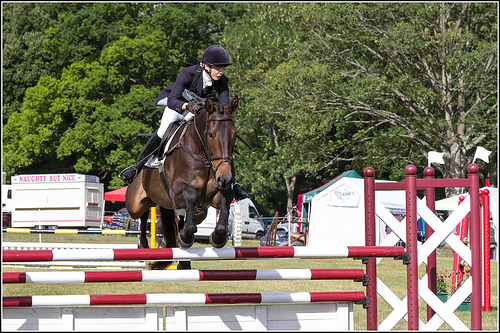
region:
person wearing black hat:
[161, 42, 228, 119]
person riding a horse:
[136, 40, 253, 245]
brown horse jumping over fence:
[126, 102, 251, 252]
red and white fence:
[7, 240, 357, 327]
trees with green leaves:
[10, 10, 150, 155]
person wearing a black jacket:
[168, 37, 235, 121]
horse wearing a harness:
[193, 95, 240, 187]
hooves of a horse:
[171, 218, 233, 253]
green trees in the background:
[245, 3, 496, 173]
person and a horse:
[125, 40, 242, 257]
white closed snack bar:
[9, 165, 114, 240]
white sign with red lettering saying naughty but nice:
[10, 169, 87, 186]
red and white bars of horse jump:
[7, 236, 414, 304]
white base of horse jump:
[3, 296, 365, 330]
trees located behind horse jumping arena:
[251, 11, 485, 305]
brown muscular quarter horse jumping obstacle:
[123, 93, 255, 275]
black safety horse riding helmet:
[194, 39, 236, 76]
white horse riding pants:
[144, 100, 205, 153]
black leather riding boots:
[115, 127, 167, 186]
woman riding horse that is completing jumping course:
[112, 32, 281, 297]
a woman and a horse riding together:
[124, 45, 245, 253]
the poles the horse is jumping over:
[7, 240, 407, 307]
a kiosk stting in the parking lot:
[6, 168, 101, 226]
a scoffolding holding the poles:
[360, 163, 479, 331]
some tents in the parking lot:
[296, 166, 368, 248]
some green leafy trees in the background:
[2, 5, 499, 187]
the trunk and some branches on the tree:
[406, 13, 492, 178]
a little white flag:
[422, 143, 446, 168]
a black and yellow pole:
[8, 220, 150, 242]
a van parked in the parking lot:
[236, 197, 266, 229]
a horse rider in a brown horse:
[100, 25, 262, 258]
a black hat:
[187, 34, 239, 90]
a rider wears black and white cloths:
[112, 40, 245, 184]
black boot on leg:
[116, 129, 169, 184]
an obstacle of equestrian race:
[0, 159, 497, 331]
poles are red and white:
[9, 238, 403, 317]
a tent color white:
[301, 159, 433, 257]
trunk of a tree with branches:
[328, 5, 495, 191]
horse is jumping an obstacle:
[114, 90, 259, 255]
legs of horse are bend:
[127, 180, 244, 248]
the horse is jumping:
[109, 30, 262, 246]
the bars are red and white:
[0, 217, 371, 329]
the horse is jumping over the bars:
[1, 115, 351, 307]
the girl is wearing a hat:
[182, 43, 251, 83]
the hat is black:
[197, 32, 234, 75]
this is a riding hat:
[185, 35, 240, 70]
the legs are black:
[150, 187, 245, 243]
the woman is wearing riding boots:
[107, 125, 162, 182]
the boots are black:
[102, 126, 172, 181]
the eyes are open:
[195, 116, 245, 146]